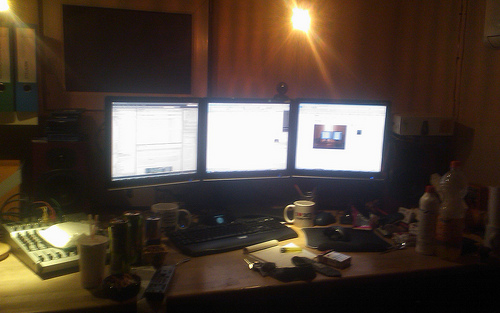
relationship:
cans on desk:
[105, 211, 149, 272] [2, 197, 499, 312]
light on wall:
[279, 2, 323, 43] [206, 3, 498, 114]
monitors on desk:
[99, 95, 399, 192] [2, 197, 499, 312]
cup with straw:
[77, 232, 110, 293] [87, 214, 102, 239]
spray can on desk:
[415, 183, 442, 254] [2, 197, 499, 312]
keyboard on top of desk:
[165, 215, 297, 256] [2, 197, 499, 312]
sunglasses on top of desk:
[340, 209, 373, 224] [2, 197, 499, 312]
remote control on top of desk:
[146, 261, 174, 301] [2, 197, 499, 312]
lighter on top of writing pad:
[279, 244, 306, 254] [240, 236, 317, 272]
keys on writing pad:
[242, 255, 270, 282] [240, 236, 317, 272]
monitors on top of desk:
[99, 95, 399, 192] [2, 197, 499, 312]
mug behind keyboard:
[283, 200, 319, 230] [165, 215, 297, 256]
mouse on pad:
[321, 224, 355, 248] [296, 223, 396, 253]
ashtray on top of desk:
[99, 270, 142, 298] [2, 197, 499, 312]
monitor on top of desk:
[104, 97, 202, 186] [2, 197, 499, 312]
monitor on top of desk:
[206, 100, 292, 176] [2, 197, 499, 312]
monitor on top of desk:
[294, 98, 391, 183] [2, 197, 499, 312]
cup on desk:
[77, 232, 110, 293] [2, 197, 499, 312]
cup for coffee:
[77, 232, 110, 293] [78, 238, 96, 252]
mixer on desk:
[75, 233, 105, 294] [2, 197, 499, 312]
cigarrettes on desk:
[314, 247, 352, 269] [2, 197, 499, 312]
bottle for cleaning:
[415, 183, 442, 254] [422, 181, 440, 264]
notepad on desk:
[240, 236, 317, 272] [2, 197, 499, 312]